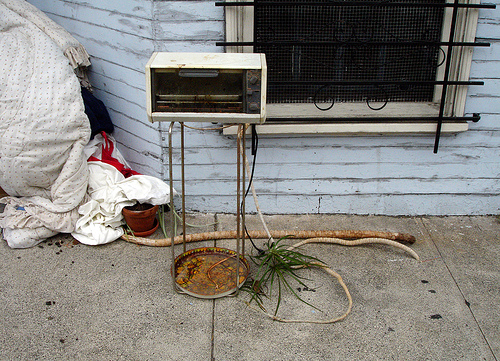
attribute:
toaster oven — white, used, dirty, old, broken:
[146, 51, 269, 125]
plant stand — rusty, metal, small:
[168, 121, 251, 300]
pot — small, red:
[123, 203, 160, 236]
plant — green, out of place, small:
[248, 234, 329, 321]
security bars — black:
[214, 0, 498, 156]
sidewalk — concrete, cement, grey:
[1, 212, 498, 360]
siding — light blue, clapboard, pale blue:
[25, 1, 499, 218]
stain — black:
[430, 313, 442, 321]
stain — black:
[427, 287, 436, 294]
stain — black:
[420, 276, 429, 285]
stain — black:
[386, 326, 395, 334]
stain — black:
[60, 337, 66, 344]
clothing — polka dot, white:
[2, 2, 179, 246]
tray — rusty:
[170, 245, 252, 299]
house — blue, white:
[26, 0, 500, 219]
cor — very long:
[240, 126, 352, 324]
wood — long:
[119, 228, 416, 248]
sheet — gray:
[156, 85, 243, 102]